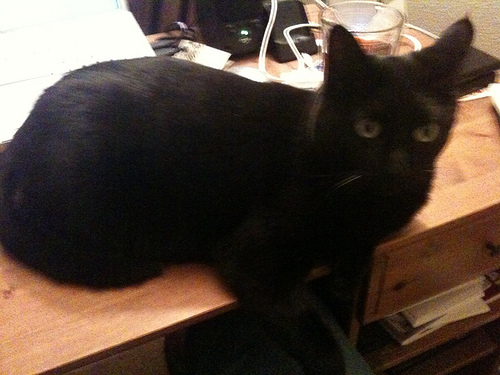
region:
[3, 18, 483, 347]
this is a cat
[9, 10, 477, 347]
this is a black cat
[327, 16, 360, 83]
this is a cat's ear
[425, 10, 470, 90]
this is a cat's ear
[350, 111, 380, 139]
this is a cat's eye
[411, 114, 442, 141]
this is a cat ear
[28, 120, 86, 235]
this is a black in colour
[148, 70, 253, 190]
this is a black in colour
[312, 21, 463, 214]
this is a cat's head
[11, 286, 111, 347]
this is a brown in colour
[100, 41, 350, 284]
this is a cat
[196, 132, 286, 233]
the cat is black in color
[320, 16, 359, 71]
this is the ear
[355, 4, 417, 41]
this is a glass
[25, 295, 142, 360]
this is a table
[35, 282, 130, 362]
the table is brown in color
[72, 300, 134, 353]
the table is wooden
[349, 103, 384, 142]
this is the eye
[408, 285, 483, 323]
this is a book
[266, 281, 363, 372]
this is the leg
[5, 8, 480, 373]
this cat is out of focus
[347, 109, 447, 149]
cat's eyes are gold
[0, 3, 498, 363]
cat is perched on a desk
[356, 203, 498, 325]
desk has one pull-out drawer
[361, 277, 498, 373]
desk has open shelving under the drawer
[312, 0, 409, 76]
a cup of liquid behind the cat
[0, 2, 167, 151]
laptop screen fuzzily visible behind the cat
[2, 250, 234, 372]
desk is finished wood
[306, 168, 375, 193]
black cat has white whiskers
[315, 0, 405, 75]
the liquid in the cup looks like cola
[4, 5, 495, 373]
a black cat on a desk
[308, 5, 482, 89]
the cat has pointy ears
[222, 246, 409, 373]
front legs of cat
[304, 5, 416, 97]
a glass behind a cat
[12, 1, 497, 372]
the desk is color brown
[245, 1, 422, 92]
the wires are gray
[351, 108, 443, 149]
eyes of cat are round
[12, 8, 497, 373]
cat sits on edge of desk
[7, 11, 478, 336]
this is a cat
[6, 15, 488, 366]
this is a black cat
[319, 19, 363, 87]
this is a cat's ear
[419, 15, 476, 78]
this is a cat's ear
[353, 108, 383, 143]
this is a cat's eye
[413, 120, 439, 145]
this is a cat's eye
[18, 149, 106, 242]
this is black in colour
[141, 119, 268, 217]
this is black in colour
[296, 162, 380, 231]
this is black in colour